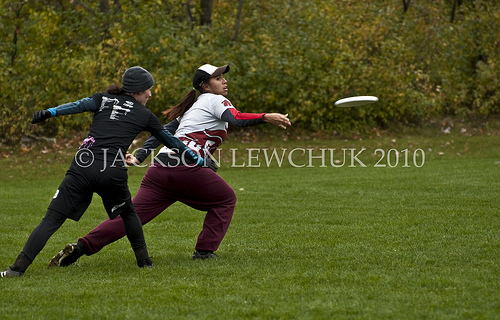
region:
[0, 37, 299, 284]
two people on the grass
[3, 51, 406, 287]
two people playing with a Frisbee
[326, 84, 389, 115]
thin white Frisbee in the air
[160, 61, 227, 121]
long ponytail sticking out of the hat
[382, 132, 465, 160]
leaves in the grass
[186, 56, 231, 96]
black and whtie cap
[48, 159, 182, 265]
leg outstretched behind the body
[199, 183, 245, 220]
knee bent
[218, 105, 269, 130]
red and white sleeve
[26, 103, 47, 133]
black glove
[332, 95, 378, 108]
a white Frisbee in the air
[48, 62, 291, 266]
a woman in burgundy sweatpants reaching for the Frisbee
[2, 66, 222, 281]
a woman in black and blue behind the woman in burgundy sweatpants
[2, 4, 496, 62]
leaves on the trees showing the sign of fall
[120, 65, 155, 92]
wool winter hat on the woman's head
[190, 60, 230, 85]
cap with visor on the woman's head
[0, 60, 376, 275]
two women playing Frisbee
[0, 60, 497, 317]
women playing Frisbee at a park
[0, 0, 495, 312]
two women playing a game of Frisbee in the fall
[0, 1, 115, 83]
green and yellow leaves on the trees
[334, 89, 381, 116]
frisbee in the air.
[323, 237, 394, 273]
grass on the ground.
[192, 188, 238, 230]
maroon pants on girl.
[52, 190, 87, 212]
black shorts on person.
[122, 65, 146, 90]
stocking cap on person.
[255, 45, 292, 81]
leaves on the tree.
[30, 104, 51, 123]
glove on person's hand.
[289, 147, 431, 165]
writing across the photo.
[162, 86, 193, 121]
pony tail in girl's hair.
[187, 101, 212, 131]
white shirt on girl.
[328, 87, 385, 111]
White frisbee in the air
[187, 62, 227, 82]
Brown and white hat on a girl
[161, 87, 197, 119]
Girl's brown pony tail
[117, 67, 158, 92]
Grey cap on a woman's head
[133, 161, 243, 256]
Woman wearing maroon sweat pants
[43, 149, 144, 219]
Woman wearing black shorts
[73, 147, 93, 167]
Copyright symbol on a woman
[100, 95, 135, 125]
White letters on a woman's shirt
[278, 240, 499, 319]
Green grass in a field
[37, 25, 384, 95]
Green leaves on trees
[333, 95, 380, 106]
white frisbee in the air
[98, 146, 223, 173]
white text reading Jackson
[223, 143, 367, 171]
white text reading Lewchuk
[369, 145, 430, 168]
white text reading 2010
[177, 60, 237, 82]
black and white cap on the young woman's head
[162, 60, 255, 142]
young woman wearing her in a ponytail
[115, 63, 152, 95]
beanie on the woman's head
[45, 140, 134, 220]
black shorts on the woman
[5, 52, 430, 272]
two women playing frisbee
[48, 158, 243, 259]
burgundy pants on the young woman